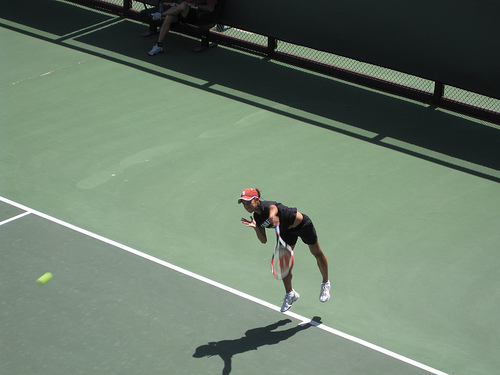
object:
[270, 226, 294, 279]
racket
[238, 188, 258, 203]
hat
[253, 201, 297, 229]
shirt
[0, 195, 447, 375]
lines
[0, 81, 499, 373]
court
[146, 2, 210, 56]
person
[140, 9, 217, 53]
bench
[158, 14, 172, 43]
legs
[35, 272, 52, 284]
ball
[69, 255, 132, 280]
motion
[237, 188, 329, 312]
player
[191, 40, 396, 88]
shadow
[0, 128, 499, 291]
ground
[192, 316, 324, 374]
shadow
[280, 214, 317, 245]
shorts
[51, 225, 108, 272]
air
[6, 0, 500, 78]
back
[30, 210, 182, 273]
baseline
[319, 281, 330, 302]
tennis shoes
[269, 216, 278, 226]
hand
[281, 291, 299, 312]
sneakers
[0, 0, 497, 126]
fence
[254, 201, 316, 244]
clothing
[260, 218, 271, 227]
writing